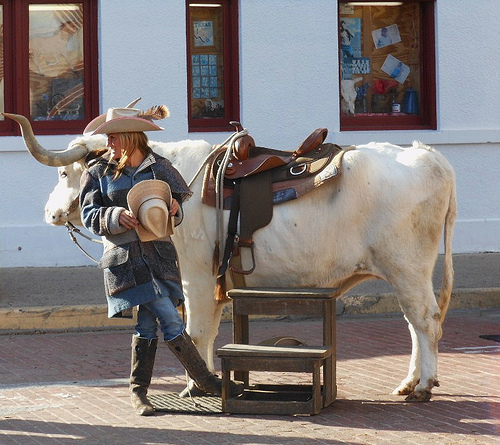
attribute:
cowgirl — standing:
[76, 106, 246, 416]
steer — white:
[5, 97, 457, 404]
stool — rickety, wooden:
[218, 284, 343, 416]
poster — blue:
[189, 16, 220, 50]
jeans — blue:
[134, 276, 185, 341]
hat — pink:
[79, 106, 162, 139]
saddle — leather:
[216, 118, 343, 276]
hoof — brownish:
[405, 387, 435, 405]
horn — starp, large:
[1, 110, 89, 167]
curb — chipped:
[2, 286, 498, 337]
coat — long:
[77, 147, 193, 319]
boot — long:
[168, 325, 247, 399]